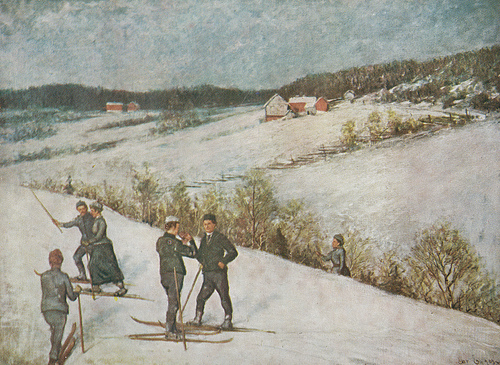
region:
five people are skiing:
[62, 206, 241, 349]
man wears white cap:
[149, 211, 174, 241]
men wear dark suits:
[149, 240, 227, 271]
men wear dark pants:
[155, 263, 251, 317]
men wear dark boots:
[152, 298, 234, 335]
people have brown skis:
[115, 301, 216, 357]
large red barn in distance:
[260, 82, 327, 134]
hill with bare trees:
[187, 166, 467, 325]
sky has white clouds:
[45, 7, 282, 69]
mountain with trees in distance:
[320, 58, 494, 117]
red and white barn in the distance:
[259, 77, 336, 130]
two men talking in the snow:
[139, 206, 251, 347]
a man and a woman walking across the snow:
[64, 174, 136, 299]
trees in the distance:
[340, 107, 427, 150]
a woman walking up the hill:
[319, 225, 356, 282]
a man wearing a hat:
[156, 201, 196, 283]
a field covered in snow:
[354, 156, 475, 209]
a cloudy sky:
[71, 5, 273, 60]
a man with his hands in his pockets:
[191, 211, 233, 285]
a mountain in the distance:
[21, 67, 105, 137]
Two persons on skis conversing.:
[131, 210, 264, 352]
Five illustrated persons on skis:
[13, 185, 270, 363]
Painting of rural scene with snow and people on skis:
[2, 46, 498, 363]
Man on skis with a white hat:
[129, 214, 221, 348]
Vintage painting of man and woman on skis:
[34, 193, 144, 301]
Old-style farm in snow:
[254, 80, 376, 124]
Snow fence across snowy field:
[128, 107, 483, 204]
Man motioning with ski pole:
[27, 182, 123, 295]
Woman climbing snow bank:
[298, 205, 390, 308]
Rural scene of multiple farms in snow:
[82, 78, 408, 126]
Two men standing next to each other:
[147, 201, 244, 341]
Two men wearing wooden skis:
[160, 216, 240, 349]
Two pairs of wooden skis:
[132, 307, 251, 358]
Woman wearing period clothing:
[326, 236, 348, 281]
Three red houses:
[266, 85, 329, 120]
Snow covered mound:
[22, 206, 385, 355]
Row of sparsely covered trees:
[106, 167, 498, 306]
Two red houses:
[106, 97, 148, 113]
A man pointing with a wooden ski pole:
[25, 180, 102, 277]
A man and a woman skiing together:
[62, 207, 131, 305]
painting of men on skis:
[131, 213, 271, 351]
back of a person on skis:
[35, 251, 91, 363]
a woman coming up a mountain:
[315, 233, 352, 279]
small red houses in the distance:
[103, 100, 140, 114]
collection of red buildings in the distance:
[263, 93, 328, 120]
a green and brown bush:
[405, 226, 498, 319]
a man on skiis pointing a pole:
[28, 189, 91, 286]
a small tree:
[237, 173, 268, 250]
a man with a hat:
[162, 216, 182, 236]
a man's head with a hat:
[200, 214, 217, 234]